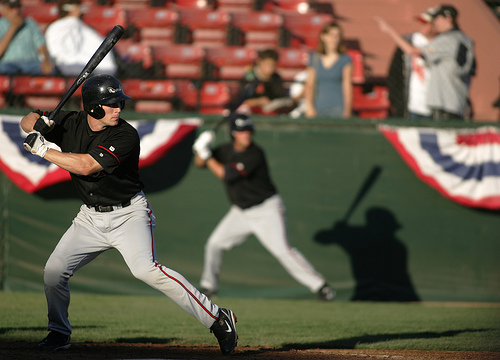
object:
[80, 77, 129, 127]
head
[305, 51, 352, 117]
dress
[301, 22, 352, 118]
woman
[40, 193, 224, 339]
pants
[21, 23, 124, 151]
bat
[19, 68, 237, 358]
man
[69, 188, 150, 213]
belt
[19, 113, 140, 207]
shirt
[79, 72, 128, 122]
helmet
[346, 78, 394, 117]
chairs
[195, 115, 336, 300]
man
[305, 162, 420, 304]
shadow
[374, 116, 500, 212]
bunting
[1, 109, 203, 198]
bunting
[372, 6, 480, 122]
man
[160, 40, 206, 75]
seat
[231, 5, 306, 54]
seat